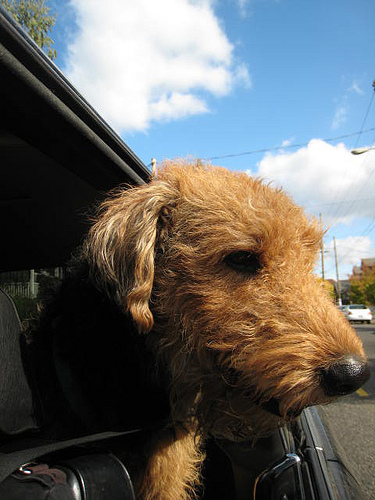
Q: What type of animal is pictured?
A: Dog.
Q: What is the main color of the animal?
A: Brown.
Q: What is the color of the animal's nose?
A: Black.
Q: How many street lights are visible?
A: One.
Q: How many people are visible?
A: None.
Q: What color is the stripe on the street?
A: Yellow.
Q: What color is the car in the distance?
A: White.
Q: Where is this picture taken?
A: On the street.